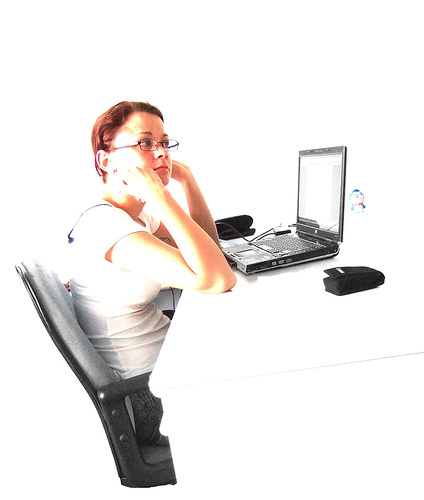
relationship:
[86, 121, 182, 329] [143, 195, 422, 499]
girl at desk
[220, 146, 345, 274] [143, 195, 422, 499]
computer on desk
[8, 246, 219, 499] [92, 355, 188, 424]
chair has arm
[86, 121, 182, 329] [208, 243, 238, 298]
girl has elbows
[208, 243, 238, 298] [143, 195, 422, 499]
elbows on desk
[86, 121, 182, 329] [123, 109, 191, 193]
girl has face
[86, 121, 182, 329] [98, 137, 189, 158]
girl has glasses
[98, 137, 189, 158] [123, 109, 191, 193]
glasses on face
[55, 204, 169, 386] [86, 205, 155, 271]
shirt has sleeve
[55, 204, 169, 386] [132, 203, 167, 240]
shirt has sleeve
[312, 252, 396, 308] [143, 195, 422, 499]
case on desk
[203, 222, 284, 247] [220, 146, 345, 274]
wires near computer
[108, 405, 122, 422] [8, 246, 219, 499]
bolt on chair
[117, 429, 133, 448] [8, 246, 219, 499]
bolt on chair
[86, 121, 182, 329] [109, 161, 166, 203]
girl has hand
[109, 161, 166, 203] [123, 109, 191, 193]
hand touching face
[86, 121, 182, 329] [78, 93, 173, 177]
girl has hair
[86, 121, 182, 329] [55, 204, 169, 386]
girl wearing shirt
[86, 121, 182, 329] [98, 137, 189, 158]
girl wearing glasses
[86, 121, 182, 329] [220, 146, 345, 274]
girl has computer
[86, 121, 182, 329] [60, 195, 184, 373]
girl wearing blouse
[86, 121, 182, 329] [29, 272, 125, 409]
girl sitting in chair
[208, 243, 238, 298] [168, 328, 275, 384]
elbows resting on desk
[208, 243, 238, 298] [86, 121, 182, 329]
elbows on girl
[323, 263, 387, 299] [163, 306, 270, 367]
cell phone on desk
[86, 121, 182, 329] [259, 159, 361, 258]
girl sitting at computer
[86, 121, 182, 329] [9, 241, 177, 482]
girl sitting in chair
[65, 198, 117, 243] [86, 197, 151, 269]
ear buds over shoulder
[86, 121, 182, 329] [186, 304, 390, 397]
girl sitting at desk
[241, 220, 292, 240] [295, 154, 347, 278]
cords going to laptop